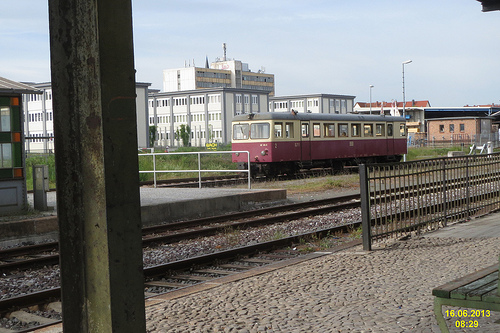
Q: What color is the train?
A: Red and yellow.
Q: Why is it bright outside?
A: Daytime.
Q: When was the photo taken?
A: Daytime.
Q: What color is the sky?
A: Blue and white.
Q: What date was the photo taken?
A: 16/06/2013.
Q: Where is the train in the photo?
A: Center.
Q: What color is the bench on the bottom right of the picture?
A: Green.